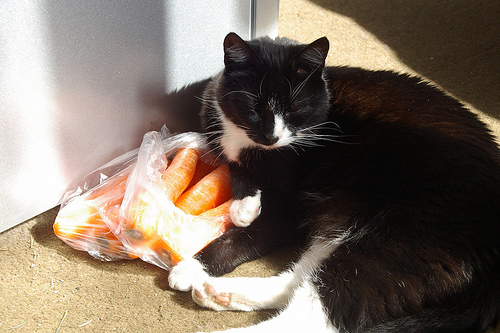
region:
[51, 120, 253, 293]
the carrots are orange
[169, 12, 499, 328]
the cat is black and white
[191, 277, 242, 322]
the cats paws are padded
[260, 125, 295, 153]
the nose of the cat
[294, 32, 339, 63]
the ears of the cat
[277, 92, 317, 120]
the eyes are closed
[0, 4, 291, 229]
the fridge is in the background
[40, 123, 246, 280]
the carrots are in a bag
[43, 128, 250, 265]
the carrots are long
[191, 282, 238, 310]
the pads of the cats feet are pink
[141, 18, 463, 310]
a black and white cat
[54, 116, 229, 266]
a few carrots in a plastic bag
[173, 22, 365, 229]
a cats white foot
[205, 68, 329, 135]
a cat with his eyes closed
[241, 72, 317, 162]
a cat with a white nose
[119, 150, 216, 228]
a carrot in a plastic bag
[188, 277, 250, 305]
the bottom of a cats foot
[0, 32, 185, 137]
a shadow on a wall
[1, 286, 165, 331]
twigs and grass on a carpet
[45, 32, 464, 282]
a cat laying on a plastic bag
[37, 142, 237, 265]
a bag or carrots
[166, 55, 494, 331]
a cat is sitting on the floor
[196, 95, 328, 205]
the cat is black and white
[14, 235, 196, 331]
the floor is carpet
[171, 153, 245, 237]
the carrots are orange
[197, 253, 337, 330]
the cats leg is white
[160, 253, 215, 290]
the cats paw is white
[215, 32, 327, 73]
the cat has ears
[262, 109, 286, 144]
the cats has white on his nose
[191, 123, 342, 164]
the cat has whiskers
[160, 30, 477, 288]
The cat is standing by the carrots.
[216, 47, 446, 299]
The cat is black and white.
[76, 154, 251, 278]
the carrots is in the bag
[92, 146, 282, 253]
The carrots are orange.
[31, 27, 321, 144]
The cat is standing by the refrigerator.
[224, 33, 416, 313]
the cat is sitting on the floor.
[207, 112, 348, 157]
the cat has long whiskers.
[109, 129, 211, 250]
The carrots is long and orange.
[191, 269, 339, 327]
The cat's paw is white.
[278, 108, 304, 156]
Part of the cat's face is white.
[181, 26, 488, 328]
a cat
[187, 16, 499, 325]
the cat is laying on a bag of carrots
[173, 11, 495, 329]
the cat's eyes are closed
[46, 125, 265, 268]
carrots are in a plastic bag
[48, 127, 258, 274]
the bag of carrots is open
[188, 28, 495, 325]
the cat has white paws and white markings on it's face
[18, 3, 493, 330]
it is sunny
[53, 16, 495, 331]
the cat is leaning on the carrots